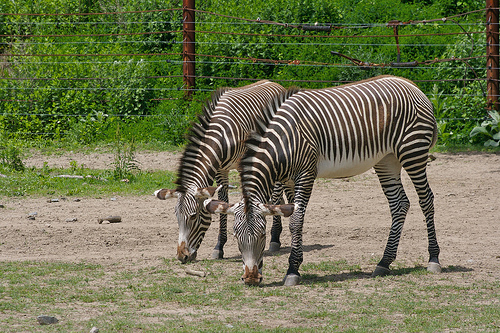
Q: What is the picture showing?
A: It is showing a field.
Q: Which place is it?
A: It is a field.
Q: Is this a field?
A: Yes, it is a field.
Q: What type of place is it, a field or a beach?
A: It is a field.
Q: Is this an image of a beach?
A: No, the picture is showing a field.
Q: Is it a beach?
A: No, it is a field.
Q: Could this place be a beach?
A: No, it is a field.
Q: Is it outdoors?
A: Yes, it is outdoors.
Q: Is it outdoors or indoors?
A: It is outdoors.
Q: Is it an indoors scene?
A: No, it is outdoors.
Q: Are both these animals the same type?
A: Yes, all the animals are zebras.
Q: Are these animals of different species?
A: No, all the animals are zebras.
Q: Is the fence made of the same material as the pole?
A: Yes, both the fence and the pole are made of metal.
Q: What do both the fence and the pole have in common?
A: The material, both the fence and the pole are metallic.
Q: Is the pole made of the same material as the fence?
A: Yes, both the pole and the fence are made of metal.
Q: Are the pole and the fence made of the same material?
A: Yes, both the pole and the fence are made of metal.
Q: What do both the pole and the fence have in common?
A: The material, both the pole and the fence are metallic.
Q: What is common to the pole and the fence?
A: The material, both the pole and the fence are metallic.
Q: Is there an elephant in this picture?
A: No, there are no elephants.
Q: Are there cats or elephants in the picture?
A: No, there are no elephants or cats.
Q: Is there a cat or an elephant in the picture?
A: No, there are no elephants or cats.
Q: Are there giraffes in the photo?
A: No, there are no giraffes.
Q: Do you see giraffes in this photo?
A: No, there are no giraffes.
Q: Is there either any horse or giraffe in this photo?
A: No, there are no giraffes or horses.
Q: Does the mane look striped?
A: Yes, the mane is striped.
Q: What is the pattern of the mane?
A: The mane is striped.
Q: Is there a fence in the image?
A: Yes, there is a fence.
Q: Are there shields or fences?
A: Yes, there is a fence.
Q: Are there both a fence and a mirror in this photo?
A: No, there is a fence but no mirrors.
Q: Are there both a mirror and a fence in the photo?
A: No, there is a fence but no mirrors.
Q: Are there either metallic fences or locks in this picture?
A: Yes, there is a metal fence.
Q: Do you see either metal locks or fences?
A: Yes, there is a metal fence.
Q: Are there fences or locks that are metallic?
A: Yes, the fence is metallic.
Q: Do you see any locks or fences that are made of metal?
A: Yes, the fence is made of metal.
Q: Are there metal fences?
A: Yes, there is a fence that is made of metal.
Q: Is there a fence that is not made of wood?
A: Yes, there is a fence that is made of metal.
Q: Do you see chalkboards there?
A: No, there are no chalkboards.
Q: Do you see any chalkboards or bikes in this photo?
A: No, there are no chalkboards or bikes.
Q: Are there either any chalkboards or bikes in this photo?
A: No, there are no chalkboards or bikes.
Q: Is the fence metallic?
A: Yes, the fence is metallic.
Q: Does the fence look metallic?
A: Yes, the fence is metallic.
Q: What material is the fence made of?
A: The fence is made of metal.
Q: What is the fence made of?
A: The fence is made of metal.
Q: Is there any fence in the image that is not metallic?
A: No, there is a fence but it is metallic.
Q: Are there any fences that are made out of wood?
A: No, there is a fence but it is made of metal.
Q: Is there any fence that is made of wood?
A: No, there is a fence but it is made of metal.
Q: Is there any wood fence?
A: No, there is a fence but it is made of metal.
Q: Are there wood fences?
A: No, there is a fence but it is made of metal.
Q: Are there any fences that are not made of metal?
A: No, there is a fence but it is made of metal.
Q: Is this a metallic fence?
A: Yes, this is a metallic fence.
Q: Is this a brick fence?
A: No, this is a metallic fence.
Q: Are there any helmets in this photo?
A: No, there are no helmets.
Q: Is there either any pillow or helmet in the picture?
A: No, there are no helmets or pillows.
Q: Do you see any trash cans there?
A: No, there are no trash cans.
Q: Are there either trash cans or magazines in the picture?
A: No, there are no trash cans or magazines.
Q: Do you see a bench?
A: No, there are no benches.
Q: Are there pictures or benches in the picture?
A: No, there are no benches or pictures.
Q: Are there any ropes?
A: No, there are no ropes.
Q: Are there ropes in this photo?
A: No, there are no ropes.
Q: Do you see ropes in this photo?
A: No, there are no ropes.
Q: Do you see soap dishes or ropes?
A: No, there are no ropes or soap dishes.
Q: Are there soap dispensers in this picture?
A: No, there are no soap dispensers.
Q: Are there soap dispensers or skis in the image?
A: No, there are no soap dispensers or skis.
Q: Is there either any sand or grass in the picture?
A: Yes, there is grass.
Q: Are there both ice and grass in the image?
A: No, there is grass but no ice.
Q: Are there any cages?
A: No, there are no cages.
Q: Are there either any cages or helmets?
A: No, there are no cages or helmets.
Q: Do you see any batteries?
A: No, there are no batteries.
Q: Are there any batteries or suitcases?
A: No, there are no batteries or suitcases.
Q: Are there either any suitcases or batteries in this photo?
A: No, there are no batteries or suitcases.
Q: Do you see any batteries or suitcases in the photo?
A: No, there are no batteries or suitcases.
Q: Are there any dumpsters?
A: No, there are no dumpsters.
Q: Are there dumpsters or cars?
A: No, there are no dumpsters or cars.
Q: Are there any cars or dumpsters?
A: No, there are no dumpsters or cars.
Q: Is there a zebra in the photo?
A: Yes, there is a zebra.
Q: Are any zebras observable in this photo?
A: Yes, there is a zebra.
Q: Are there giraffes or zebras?
A: Yes, there is a zebra.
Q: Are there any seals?
A: No, there are no seals.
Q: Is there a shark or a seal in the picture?
A: No, there are no seals or sharks.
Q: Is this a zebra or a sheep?
A: This is a zebra.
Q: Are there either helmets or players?
A: No, there are no helmets or players.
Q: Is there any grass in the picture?
A: Yes, there is grass.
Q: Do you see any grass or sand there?
A: Yes, there is grass.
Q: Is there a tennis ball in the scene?
A: No, there are no tennis balls.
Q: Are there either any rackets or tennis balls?
A: No, there are no tennis balls or rackets.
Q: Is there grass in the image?
A: Yes, there is grass.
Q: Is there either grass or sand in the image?
A: Yes, there is grass.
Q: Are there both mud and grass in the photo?
A: No, there is grass but no mud.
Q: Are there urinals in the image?
A: No, there are no urinals.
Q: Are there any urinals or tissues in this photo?
A: No, there are no urinals or tissues.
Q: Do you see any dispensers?
A: No, there are no dispensers.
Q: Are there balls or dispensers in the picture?
A: No, there are no dispensers or balls.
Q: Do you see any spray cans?
A: No, there are no spray cans.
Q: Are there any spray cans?
A: No, there are no spray cans.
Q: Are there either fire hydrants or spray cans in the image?
A: No, there are no spray cans or fire hydrants.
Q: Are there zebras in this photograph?
A: Yes, there is a zebra.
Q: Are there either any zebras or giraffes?
A: Yes, there is a zebra.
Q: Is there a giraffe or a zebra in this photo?
A: Yes, there is a zebra.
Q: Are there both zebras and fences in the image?
A: Yes, there are both a zebra and a fence.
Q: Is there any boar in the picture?
A: No, there are no boars.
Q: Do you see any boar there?
A: No, there are no boars.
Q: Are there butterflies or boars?
A: No, there are no boars or butterflies.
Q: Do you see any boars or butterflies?
A: No, there are no boars or butterflies.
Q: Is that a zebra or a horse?
A: That is a zebra.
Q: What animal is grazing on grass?
A: The zebra is grazing on grass.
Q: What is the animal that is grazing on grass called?
A: The animal is a zebra.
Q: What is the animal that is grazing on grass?
A: The animal is a zebra.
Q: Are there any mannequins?
A: No, there are no mannequins.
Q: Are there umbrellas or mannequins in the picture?
A: No, there are no mannequins or umbrellas.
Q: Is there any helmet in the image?
A: No, there are no helmets.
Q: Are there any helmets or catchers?
A: No, there are no helmets or catchers.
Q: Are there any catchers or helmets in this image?
A: No, there are no helmets or catchers.